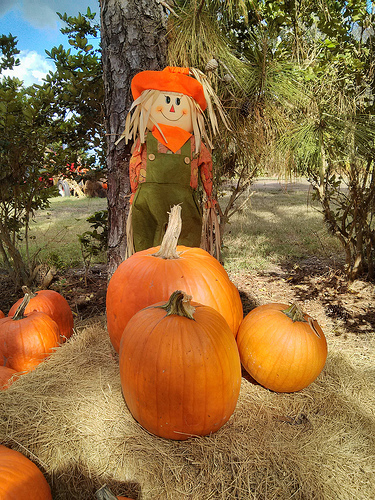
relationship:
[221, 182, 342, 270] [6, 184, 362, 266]
shadow on grass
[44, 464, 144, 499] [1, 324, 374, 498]
shadow on grass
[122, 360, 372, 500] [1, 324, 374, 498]
shadow on grass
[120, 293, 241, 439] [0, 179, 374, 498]
pumpkin in a patch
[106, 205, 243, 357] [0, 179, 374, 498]
pumpkin in a patch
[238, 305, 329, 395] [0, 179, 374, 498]
pumpkin in a patch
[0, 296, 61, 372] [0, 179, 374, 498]
pumpkin in a patch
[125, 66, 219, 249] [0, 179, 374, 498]
scarecrow in a patch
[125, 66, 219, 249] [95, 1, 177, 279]
scarecrow near a tree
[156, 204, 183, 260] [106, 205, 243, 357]
stem on a pumpkin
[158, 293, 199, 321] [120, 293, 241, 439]
stem on a pumpkin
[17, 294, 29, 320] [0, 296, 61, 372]
stem on a pumpkin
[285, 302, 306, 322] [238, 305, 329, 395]
stem on a pumpkin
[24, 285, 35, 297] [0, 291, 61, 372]
stem on a pumpkin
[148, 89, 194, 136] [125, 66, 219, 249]
face on a scarecrow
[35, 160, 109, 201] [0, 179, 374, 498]
house at a patch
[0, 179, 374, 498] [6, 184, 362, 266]
patch made of grass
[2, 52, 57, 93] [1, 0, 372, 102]
cloud in sky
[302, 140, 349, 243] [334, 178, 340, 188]
branch has leaves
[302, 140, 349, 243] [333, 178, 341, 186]
branch has leaves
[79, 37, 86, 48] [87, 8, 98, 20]
branch has leaves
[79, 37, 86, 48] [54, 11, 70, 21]
branch has leaves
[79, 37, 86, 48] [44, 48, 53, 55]
branch has leaves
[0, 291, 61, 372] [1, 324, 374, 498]
pumpkin on grass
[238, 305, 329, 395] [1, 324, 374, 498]
pumpkin on grass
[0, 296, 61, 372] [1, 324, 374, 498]
pumpkin on grass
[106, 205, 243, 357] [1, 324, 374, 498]
pumpkin on grass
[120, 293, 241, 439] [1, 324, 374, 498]
pumpkin on grass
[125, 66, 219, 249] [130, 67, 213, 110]
scarecrow wearing a hat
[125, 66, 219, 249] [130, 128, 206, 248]
scarecrow wearing overall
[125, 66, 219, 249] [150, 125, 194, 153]
scarecrow wearing a scarf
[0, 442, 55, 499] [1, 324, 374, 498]
pumpkin on grass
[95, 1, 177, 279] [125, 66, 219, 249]
tree near a scarecrow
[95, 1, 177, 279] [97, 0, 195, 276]
tree has bark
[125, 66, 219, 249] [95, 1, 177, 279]
scarecrow leans on tree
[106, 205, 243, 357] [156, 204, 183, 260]
pumpkin has a stem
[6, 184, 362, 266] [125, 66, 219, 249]
grass behind scarecrow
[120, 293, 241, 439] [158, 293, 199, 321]
pumpkin has a stem